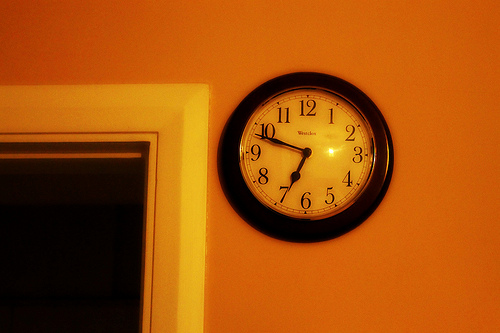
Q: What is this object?
A: Clock.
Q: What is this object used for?
A: To tell time.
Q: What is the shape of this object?
A: Circular.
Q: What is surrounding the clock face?
A: Black border.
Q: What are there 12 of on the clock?
A: Numbers.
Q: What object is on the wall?
A: Clock.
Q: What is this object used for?
A: To tell the time.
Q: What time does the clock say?
A: 6:48.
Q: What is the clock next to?
A: Doorway.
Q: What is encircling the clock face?
A: A black border.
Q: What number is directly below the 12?
A: 6.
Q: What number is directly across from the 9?
A: 3.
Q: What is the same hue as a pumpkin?
A: The wall.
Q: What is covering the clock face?
A: Glass.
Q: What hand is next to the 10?
A: Minute.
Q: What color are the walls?
A: Yellow.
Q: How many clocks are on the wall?
A: One.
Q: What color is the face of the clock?
A: White and black.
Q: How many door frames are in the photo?
A: One.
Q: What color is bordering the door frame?
A: White.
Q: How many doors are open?
A: One.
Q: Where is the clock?
A: Wall.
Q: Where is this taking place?
A: In a house.